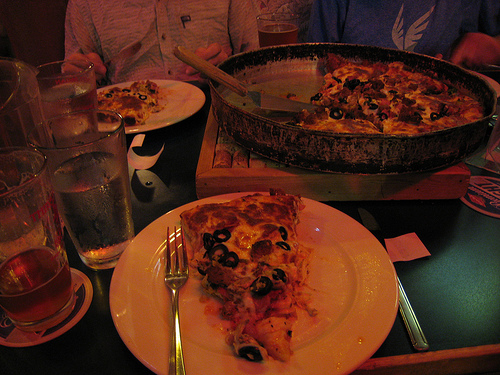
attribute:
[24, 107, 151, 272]
glass — clear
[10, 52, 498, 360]
table — green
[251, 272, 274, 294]
olive — black 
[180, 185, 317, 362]
cheese — melted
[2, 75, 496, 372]
table — green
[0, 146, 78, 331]
glass — clear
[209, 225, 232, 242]
olive — black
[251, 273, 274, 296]
olive — black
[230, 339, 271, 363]
olive — black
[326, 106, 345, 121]
olive — black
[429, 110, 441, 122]
olive — black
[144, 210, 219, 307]
fork — silver 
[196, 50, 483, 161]
pan — black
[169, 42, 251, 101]
handle — brown